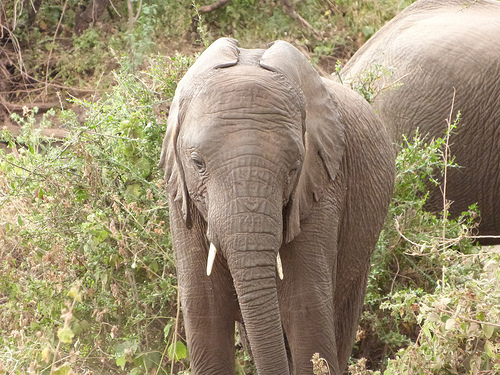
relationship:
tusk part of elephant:
[204, 241, 216, 275] [141, 37, 408, 373]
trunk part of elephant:
[221, 239, 295, 373] [141, 37, 408, 373]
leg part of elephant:
[170, 197, 236, 373] [141, 37, 408, 373]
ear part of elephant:
[158, 31, 238, 230] [141, 37, 408, 373]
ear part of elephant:
[158, 31, 243, 227] [141, 37, 408, 373]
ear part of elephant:
[255, 35, 344, 249] [156, 36, 396, 373]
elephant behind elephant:
[330, 2, 499, 246] [156, 36, 396, 373]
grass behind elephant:
[5, 7, 187, 370] [156, 36, 396, 373]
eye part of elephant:
[191, 152, 206, 172] [181, 154, 206, 179]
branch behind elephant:
[5, 86, 78, 154] [156, 31, 398, 337]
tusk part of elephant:
[204, 241, 216, 276] [156, 36, 396, 373]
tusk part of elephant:
[275, 249, 283, 279] [156, 36, 396, 373]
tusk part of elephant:
[204, 241, 216, 275] [91, 16, 449, 373]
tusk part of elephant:
[275, 249, 284, 280] [91, 16, 449, 373]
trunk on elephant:
[202, 161, 295, 374] [141, 37, 408, 373]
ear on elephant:
[158, 31, 243, 227] [156, 36, 396, 373]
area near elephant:
[13, 3, 467, 356] [115, 79, 400, 313]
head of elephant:
[170, 35, 344, 276] [156, 36, 396, 373]